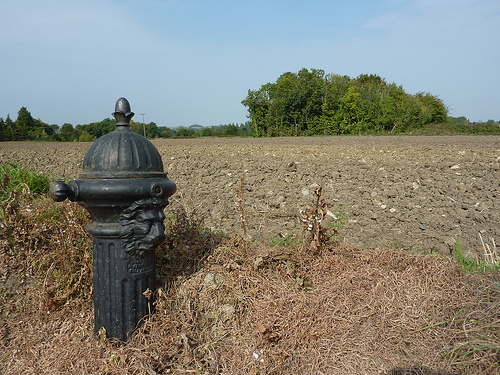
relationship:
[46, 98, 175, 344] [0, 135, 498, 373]
hydrant on hill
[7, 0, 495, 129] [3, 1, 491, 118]
cloud are in sky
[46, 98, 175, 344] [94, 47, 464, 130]
hydrant on hill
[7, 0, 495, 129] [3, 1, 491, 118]
cloud in sky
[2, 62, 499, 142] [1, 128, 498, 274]
forest surrounding farm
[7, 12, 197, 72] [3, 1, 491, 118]
cloud in sky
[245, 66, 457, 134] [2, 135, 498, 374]
trees surrounding a dry field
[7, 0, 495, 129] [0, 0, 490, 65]
cloud in sky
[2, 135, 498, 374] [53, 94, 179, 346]
dry field by hydrant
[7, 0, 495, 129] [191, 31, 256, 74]
cloud in sky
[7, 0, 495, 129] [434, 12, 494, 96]
cloud in sky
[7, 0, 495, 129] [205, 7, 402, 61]
cloud in sky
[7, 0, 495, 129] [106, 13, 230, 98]
cloud in blue sky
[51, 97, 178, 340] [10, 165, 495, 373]
pillar on hill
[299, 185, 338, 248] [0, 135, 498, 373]
weed on hill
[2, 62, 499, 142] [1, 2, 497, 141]
forest under sky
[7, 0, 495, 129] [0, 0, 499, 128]
cloud in sky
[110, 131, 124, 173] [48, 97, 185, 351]
line on post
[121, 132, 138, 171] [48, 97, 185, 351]
line on post